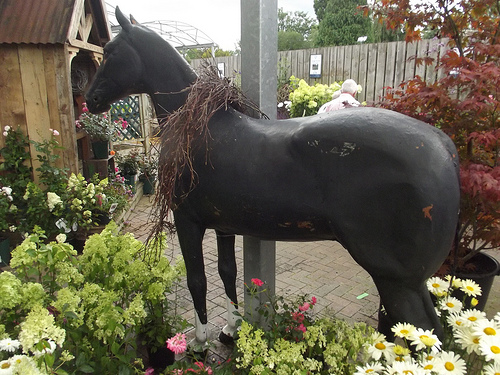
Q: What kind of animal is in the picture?
A: A horse.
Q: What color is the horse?
A: Black.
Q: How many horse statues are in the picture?
A: One.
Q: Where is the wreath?
A: The horse's neck.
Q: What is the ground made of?
A: Bricks.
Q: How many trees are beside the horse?
A: One.